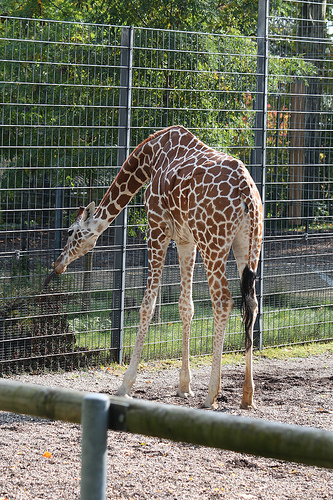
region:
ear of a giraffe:
[83, 201, 94, 219]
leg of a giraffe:
[199, 248, 232, 405]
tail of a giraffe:
[239, 195, 258, 349]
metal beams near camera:
[0, 377, 332, 498]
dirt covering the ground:
[0, 355, 332, 499]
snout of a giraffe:
[51, 260, 65, 274]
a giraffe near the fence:
[54, 123, 262, 409]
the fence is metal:
[0, 0, 332, 373]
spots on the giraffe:
[158, 155, 217, 204]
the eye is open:
[67, 229, 75, 236]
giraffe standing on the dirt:
[31, 117, 303, 436]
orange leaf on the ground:
[40, 449, 53, 460]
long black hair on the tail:
[238, 265, 260, 355]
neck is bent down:
[37, 130, 146, 307]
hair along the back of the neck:
[93, 122, 174, 208]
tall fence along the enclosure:
[1, 1, 332, 377]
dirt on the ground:
[2, 339, 332, 498]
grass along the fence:
[102, 336, 331, 386]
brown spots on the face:
[60, 229, 95, 254]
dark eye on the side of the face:
[67, 226, 74, 236]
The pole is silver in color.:
[71, 397, 117, 499]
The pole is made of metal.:
[77, 394, 111, 498]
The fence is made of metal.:
[7, 20, 113, 119]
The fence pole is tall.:
[111, 26, 132, 366]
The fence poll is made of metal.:
[109, 24, 127, 363]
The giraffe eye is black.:
[66, 229, 75, 236]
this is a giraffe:
[45, 92, 298, 406]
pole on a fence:
[13, 359, 331, 474]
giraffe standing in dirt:
[54, 341, 312, 495]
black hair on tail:
[224, 261, 277, 348]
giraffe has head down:
[21, 121, 177, 287]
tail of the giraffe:
[232, 172, 271, 352]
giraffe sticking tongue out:
[22, 226, 90, 301]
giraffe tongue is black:
[28, 261, 62, 290]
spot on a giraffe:
[190, 163, 208, 184]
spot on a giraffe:
[207, 207, 231, 229]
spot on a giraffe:
[212, 191, 233, 212]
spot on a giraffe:
[147, 194, 162, 217]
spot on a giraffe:
[151, 171, 161, 192]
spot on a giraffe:
[157, 144, 177, 163]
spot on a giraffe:
[123, 155, 140, 174]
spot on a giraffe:
[70, 234, 84, 246]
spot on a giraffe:
[212, 268, 220, 279]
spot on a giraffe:
[240, 176, 249, 191]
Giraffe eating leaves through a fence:
[52, 124, 270, 411]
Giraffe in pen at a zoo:
[52, 125, 263, 412]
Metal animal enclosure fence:
[257, 2, 331, 343]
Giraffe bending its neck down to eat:
[55, 126, 265, 410]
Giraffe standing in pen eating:
[50, 126, 262, 410]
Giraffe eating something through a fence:
[23, 147, 136, 299]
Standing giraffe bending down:
[52, 126, 263, 406]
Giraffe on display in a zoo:
[49, 124, 265, 410]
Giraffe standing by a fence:
[39, 60, 278, 421]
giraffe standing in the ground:
[49, 118, 264, 407]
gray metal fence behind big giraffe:
[0, 5, 330, 382]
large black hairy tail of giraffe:
[239, 202, 258, 352]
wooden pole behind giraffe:
[0, 379, 331, 495]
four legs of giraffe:
[98, 242, 261, 410]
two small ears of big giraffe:
[74, 200, 95, 226]